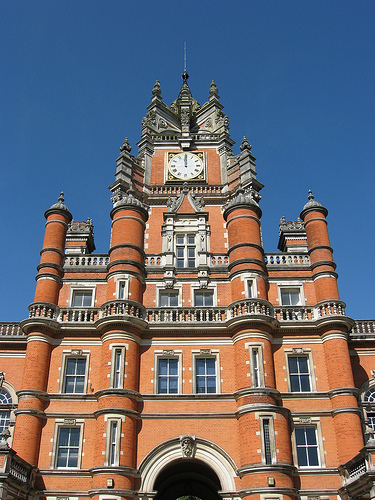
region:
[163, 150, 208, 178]
clock on the tower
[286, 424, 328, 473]
window on the building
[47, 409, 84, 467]
window on the building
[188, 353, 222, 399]
window on the building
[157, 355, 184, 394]
window on the building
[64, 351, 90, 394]
window on the building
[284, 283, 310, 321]
window on the building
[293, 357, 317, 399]
window on the building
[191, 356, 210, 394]
window on the building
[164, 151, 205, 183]
A clock with the time reading 12:00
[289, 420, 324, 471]
A single four paned window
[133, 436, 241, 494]
A circular archway with a carving at its center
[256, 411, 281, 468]
A long thin window with a cement border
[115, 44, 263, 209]
An ornate gothic clock tower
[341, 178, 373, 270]
A bright blue cloudless sky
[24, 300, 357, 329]
Decorative stone railing on the side of the building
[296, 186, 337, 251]
A pointy red brick building tower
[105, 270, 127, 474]
Three thin windows on the front of a building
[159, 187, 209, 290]
An ornate six paned window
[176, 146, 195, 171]
Black hands on clock.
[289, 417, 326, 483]
Window on front of building.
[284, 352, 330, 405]
Window on front of building.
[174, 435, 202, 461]
Statue of face on archway.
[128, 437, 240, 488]
Large archway in front of building.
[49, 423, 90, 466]
Window on front of building.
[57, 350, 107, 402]
Window on front of building.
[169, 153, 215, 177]
Clock has white face.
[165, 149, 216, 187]
Clock is round in shape.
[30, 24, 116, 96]
Sky is blue and clear.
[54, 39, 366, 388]
A tall brown tower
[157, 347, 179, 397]
A tall brown tower's window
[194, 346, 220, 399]
tall brown tower's window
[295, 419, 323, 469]
tall brown tower's window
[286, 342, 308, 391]
tall brown tower's window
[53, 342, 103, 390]
tall brown tower's window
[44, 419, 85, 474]
tall brown tower's window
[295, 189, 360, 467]
tall brown tower's pillar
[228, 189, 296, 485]
tall brown tower's pillar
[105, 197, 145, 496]
tall brown tower's pillar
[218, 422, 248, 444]
red brick on wall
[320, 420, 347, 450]
red brick on wall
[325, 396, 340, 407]
red brick on wall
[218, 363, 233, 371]
red brick on wall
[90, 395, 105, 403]
red brick on wall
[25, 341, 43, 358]
red brick on wall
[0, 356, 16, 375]
red brick on wall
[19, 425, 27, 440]
red brick on wall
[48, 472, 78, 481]
red brick on wall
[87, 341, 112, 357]
red brick on wall